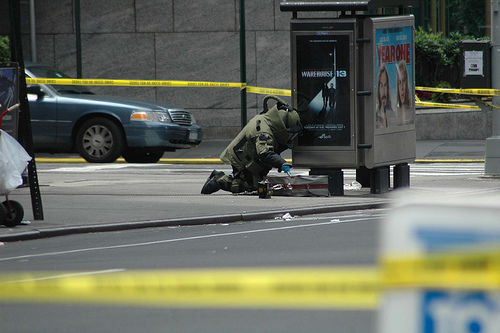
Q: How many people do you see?
A: 1.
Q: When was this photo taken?
A: During daylight.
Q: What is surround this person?
A: Yellow tape.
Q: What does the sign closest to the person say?
A: Warehouse 13.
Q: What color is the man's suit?
A: Green.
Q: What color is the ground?
A: Gray.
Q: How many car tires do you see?
A: 2.